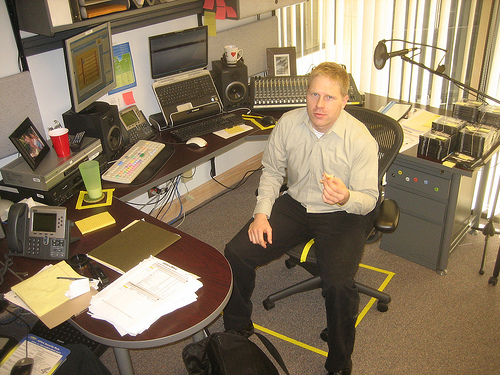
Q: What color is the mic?
A: Black.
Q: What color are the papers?
A: White.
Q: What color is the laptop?
A: Silver and black.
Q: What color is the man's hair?
A: Blonde.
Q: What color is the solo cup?
A: Red.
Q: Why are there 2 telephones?
A: There's an adjacent workstation.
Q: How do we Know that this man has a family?
A: Picture frame on the desk.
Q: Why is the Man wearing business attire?
A: He's at work.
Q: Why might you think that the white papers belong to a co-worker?
A: They're facing the co-worker's work station.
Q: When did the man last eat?
A: Right now.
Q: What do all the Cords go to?
A: Electronic equipment.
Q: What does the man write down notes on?
A: Post-its.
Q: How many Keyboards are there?
A: 2.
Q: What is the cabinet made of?
A: Metal.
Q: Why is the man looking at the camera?
A: Talking to someone.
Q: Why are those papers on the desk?
A: For business.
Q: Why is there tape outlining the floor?
A: To show where the chair should go.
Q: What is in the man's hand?
A: Food.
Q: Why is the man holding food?
A: Eating.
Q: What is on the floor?
A: Yellow tape.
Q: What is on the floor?
A: Backpack.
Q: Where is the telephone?
A: On the desk.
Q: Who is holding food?
A: The man.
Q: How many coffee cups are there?
A: One.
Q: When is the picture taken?
A: Day time.